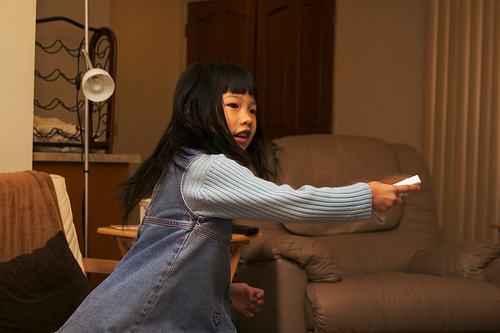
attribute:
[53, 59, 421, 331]
girl — young, asian, playing, little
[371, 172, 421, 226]
wii — white, hand held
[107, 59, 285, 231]
hair — blowing, long, dark, black, straight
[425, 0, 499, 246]
curtains — white, brown, curtain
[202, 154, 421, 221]
arm — outstretched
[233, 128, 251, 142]
mouth — open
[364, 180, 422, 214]
hand — straightened out, folded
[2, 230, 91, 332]
pillow — dark brown, brown, velvet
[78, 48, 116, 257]
lamp — standing, flexible, plain model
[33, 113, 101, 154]
linen — white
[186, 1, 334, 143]
doors — wooden, french double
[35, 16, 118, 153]
wine rack — wooden, metallic, small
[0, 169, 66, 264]
blanket — light brown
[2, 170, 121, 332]
couch — gray, single sitter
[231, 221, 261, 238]
tv remote — black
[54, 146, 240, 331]
dress — jeans, light blue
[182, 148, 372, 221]
sweater — woolen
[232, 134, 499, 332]
chair — brown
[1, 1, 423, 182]
wall — brown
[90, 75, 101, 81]
bulb holder — white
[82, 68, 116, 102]
lampshade — white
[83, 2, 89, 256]
shand — metal, silver, long, thin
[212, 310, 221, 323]
badge — small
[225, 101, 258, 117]
these — eyes